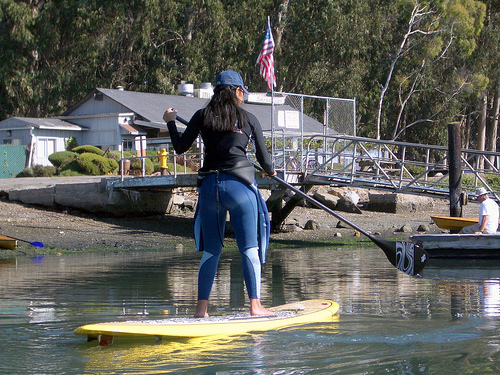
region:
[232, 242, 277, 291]
white stripe on blue pants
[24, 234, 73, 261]
blue oar on the shore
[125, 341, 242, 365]
reflection of yellow device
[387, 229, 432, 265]
design on blue paddle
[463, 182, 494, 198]
white hat on man's head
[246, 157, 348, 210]
blue handle on the oar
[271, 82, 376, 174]
large fence on the shore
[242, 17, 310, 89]
large American flag on the pole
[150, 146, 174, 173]
yellow hydrant on shore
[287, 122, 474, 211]
small bridge leading to the shore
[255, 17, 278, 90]
A red, white, and blue American flag.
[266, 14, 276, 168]
A silver flagpole.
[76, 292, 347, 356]
A yellow paddle board.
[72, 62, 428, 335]
A woman standing up paddle boarding.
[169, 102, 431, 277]
A black and silver paddle.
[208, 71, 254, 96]
A blue ball cap.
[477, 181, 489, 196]
A beige hat.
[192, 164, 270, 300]
A blue wetsuit.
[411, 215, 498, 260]
A dock.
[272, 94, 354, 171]
A chain link fence.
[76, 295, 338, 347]
a yellow paddle board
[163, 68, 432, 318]
a woman standing with oar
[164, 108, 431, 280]
a long black oar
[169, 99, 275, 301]
a black and blue wet suit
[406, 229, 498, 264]
a metal row boat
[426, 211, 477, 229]
a yellow row boat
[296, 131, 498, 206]
a long metal ramp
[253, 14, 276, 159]
an American flag on pole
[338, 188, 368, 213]
a large boulder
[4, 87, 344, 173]
a white building in distance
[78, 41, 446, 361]
lady standing on a paddle board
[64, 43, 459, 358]
lady holding a black paddle stick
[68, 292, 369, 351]
yellow paddle board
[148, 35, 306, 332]
lady wearing a blue hat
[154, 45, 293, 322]
lady wearing blue swimwear pants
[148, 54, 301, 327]
lady wearing black swimwear shirt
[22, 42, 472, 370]
lady at the lake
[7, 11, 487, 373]
lady near the shore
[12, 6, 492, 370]
lady near the dock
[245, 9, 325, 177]
United States of America flag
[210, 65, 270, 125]
woman wearing a hat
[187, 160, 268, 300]
woman wearing a wet suit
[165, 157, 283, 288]
wet suit is pulled down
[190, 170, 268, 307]
the wet suit is blue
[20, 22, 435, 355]
woman is paddle boarding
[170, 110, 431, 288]
the paddle is black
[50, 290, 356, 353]
the board is yellow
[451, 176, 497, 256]
man sitting in boat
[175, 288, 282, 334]
the woman is barefoot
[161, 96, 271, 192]
woman's shirt is black